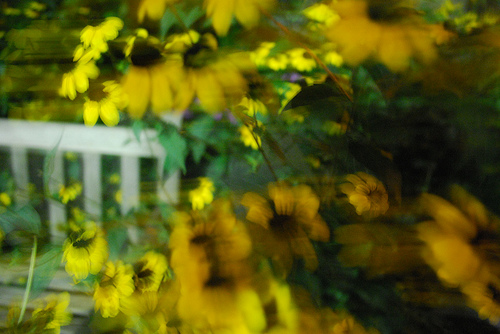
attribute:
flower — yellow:
[57, 48, 98, 93]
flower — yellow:
[70, 15, 122, 59]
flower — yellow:
[62, 227, 107, 283]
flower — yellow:
[340, 171, 388, 220]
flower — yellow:
[238, 182, 327, 272]